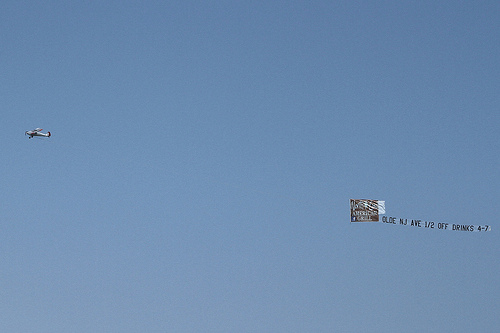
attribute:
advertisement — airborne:
[346, 194, 499, 238]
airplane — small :
[26, 124, 49, 140]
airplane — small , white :
[24, 126, 51, 140]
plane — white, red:
[13, 125, 55, 154]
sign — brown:
[337, 185, 399, 259]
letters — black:
[376, 201, 490, 243]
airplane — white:
[21, 118, 47, 150]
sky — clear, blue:
[76, 113, 232, 216]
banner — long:
[226, 120, 460, 249]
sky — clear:
[165, 169, 265, 264]